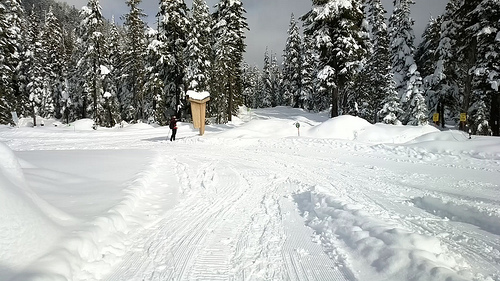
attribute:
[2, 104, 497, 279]
snow — white 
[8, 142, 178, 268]
snow — drifted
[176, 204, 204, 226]
snow — white 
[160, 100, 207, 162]
person — in black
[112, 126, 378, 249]
snow — white 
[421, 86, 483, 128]
signs — small 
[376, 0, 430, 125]
tree — snow covered, tall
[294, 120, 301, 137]
marker pole — small 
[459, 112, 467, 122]
board — yellow 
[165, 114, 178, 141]
skier — alone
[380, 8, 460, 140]
tree — green, Big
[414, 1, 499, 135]
tree — tall, snow covered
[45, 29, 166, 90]
covered tree — snow covered, tall 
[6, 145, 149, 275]
snow — white 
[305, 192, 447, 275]
snow — white 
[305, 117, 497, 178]
snow — white 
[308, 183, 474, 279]
snow — white 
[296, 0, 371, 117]
tree — tall, snow covered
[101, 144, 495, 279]
path — snowy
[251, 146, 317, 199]
snow — white 